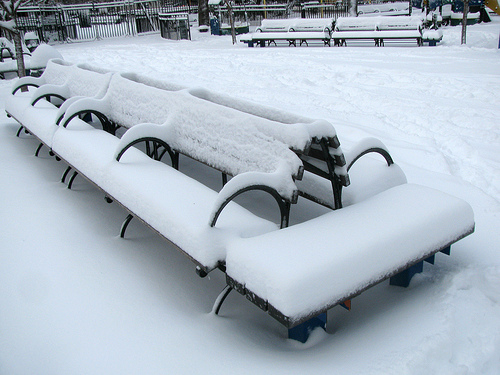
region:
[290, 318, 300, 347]
edge of a bench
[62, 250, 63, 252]
part of a snow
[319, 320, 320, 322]
side of a snow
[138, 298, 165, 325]
part of the surface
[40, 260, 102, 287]
part of the ground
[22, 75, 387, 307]
this is winter time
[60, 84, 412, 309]
the benches are covered in snow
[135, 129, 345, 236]
the benches are metal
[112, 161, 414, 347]
the snow is very deep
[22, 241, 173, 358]
the snow is very white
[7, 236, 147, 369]
the snow is very smooth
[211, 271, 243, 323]
part of a stand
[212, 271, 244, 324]
aprt of a stand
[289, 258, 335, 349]
part of a bench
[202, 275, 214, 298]
part of a metla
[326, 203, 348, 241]
aprt of a snow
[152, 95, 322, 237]
these are the benches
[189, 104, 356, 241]
the benches are filled with snow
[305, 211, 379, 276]
the snow is white in color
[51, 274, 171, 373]
the snow is all over the place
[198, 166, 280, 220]
this is the handle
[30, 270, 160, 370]
the snow is white in color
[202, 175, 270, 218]
the handle is round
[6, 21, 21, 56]
this is a tree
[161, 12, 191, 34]
this is a stand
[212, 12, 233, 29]
this is a bin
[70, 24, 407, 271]
a snow covered bench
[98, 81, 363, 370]
a snow covered bench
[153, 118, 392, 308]
a snow covered bench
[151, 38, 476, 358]
a snow covered bench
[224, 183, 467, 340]
a snow covered bench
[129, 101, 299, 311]
a snow covered bench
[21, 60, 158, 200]
a snow covered bench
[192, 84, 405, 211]
a snow covered bench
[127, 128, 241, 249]
snow on the bench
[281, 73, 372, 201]
snow on the bench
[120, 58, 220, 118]
snow on the bench